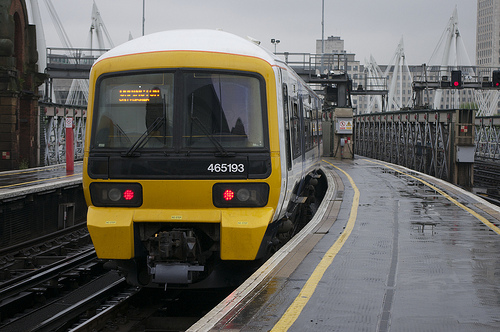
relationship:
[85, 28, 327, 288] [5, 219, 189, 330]
train on tracks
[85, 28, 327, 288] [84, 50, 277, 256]
train has front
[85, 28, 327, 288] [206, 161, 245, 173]
train has number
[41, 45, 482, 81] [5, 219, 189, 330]
bridge over tracks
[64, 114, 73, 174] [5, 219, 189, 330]
pole behind tracks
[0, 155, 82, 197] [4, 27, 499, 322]
platform in train station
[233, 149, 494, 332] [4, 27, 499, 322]
platform in train station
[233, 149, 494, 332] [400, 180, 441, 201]
platform has puddle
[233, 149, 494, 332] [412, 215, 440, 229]
platform has puddle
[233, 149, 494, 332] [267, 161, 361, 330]
platform has stripe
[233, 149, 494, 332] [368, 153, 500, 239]
platform has stripe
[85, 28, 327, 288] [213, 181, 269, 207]
train has front light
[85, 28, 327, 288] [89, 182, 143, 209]
train has front light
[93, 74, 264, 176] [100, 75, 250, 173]
window has reflection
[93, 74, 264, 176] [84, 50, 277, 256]
window in front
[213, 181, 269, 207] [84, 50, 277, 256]
front light in front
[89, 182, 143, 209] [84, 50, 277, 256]
front light in front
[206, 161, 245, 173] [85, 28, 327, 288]
number in train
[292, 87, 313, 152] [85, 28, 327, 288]
windiw on train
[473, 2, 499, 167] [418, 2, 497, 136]
building in background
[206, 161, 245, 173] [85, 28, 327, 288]
number on train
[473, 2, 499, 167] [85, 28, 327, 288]
building in left of train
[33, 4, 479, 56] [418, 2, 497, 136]
sky in background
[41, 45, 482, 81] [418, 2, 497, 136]
bridge in background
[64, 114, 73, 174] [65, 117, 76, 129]
pole has sign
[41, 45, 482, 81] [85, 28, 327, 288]
bridge behind train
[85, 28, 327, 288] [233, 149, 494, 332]
train beside platform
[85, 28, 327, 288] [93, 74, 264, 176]
train has window